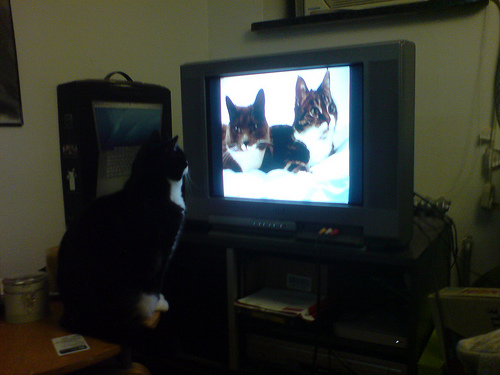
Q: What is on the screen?
A: Cats.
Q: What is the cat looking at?
A: A television.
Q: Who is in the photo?
A: Nobody.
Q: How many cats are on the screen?
A: Two.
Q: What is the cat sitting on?
A: A table.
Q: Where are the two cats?
A: On the television.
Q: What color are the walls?
A: White.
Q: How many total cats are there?
A: Three.